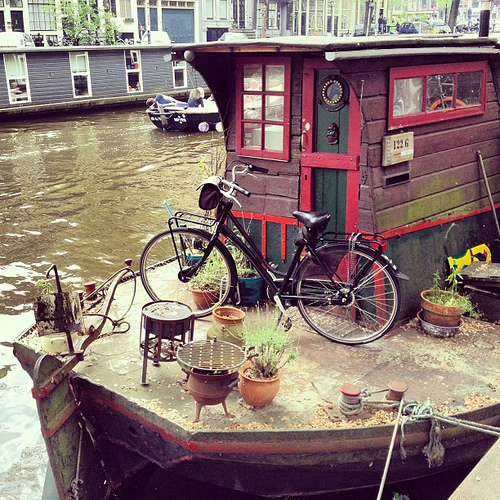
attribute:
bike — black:
[140, 160, 412, 343]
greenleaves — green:
[46, 7, 116, 45]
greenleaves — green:
[384, 0, 448, 17]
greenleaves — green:
[196, 252, 228, 289]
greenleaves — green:
[433, 276, 472, 314]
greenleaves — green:
[226, 300, 300, 382]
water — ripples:
[25, 114, 145, 211]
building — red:
[146, 12, 498, 331]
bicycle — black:
[138, 166, 407, 343]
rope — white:
[331, 380, 498, 492]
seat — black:
[289, 212, 330, 231]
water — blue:
[18, 107, 259, 349]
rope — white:
[375, 393, 404, 498]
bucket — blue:
[216, 259, 288, 309]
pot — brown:
[237, 359, 283, 408]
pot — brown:
[417, 287, 470, 328]